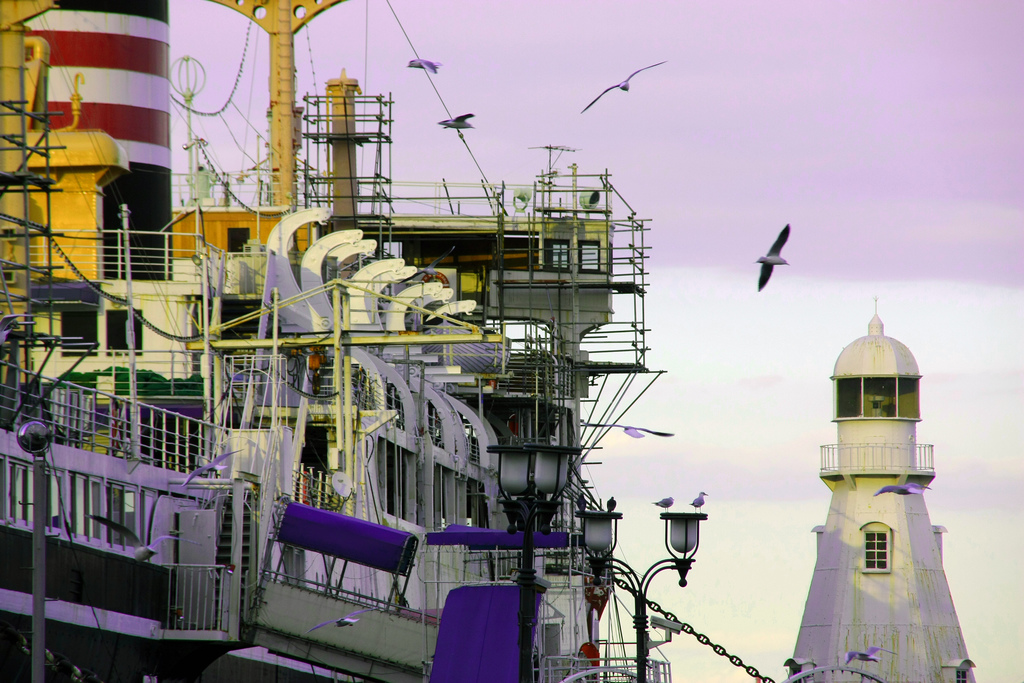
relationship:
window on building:
[191, 201, 312, 290] [115, 157, 610, 445]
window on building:
[833, 363, 870, 413] [783, 318, 974, 675]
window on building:
[845, 371, 900, 421] [772, 335, 967, 614]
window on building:
[852, 515, 896, 576] [783, 318, 974, 675]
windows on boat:
[571, 234, 598, 263] [237, 190, 633, 661]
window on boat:
[92, 297, 144, 350] [20, 245, 388, 660]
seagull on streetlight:
[658, 490, 674, 516] [576, 509, 710, 678]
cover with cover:
[277, 501, 419, 573] [286, 502, 414, 572]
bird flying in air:
[754, 222, 793, 292] [169, 1, 991, 676]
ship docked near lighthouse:
[16, 16, 656, 658] [783, 290, 976, 679]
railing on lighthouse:
[802, 421, 962, 493] [755, 317, 980, 678]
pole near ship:
[567, 488, 721, 677] [16, 16, 656, 658]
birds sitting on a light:
[574, 485, 709, 514] [576, 513, 710, 680]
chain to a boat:
[602, 548, 769, 678] [1, 4, 667, 679]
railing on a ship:
[49, 371, 227, 465] [16, 16, 656, 658]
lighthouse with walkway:
[777, 312, 972, 680] [811, 434, 945, 499]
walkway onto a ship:
[243, 479, 462, 661] [16, 16, 656, 658]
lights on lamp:
[565, 500, 708, 559] [573, 488, 717, 683]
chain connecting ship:
[593, 555, 779, 674] [16, 16, 656, 658]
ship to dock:
[16, 16, 656, 658] [666, 635, 1012, 666]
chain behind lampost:
[593, 555, 779, 674] [567, 492, 734, 678]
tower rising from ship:
[223, 4, 358, 219] [16, 16, 656, 658]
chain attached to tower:
[169, 2, 263, 121] [228, 2, 343, 203]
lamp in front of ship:
[571, 485, 716, 671] [16, 16, 656, 658]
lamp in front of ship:
[485, 421, 578, 679] [16, 16, 656, 658]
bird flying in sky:
[746, 213, 799, 300] [169, 12, 1021, 678]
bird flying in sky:
[571, 38, 660, 116] [169, 12, 1021, 678]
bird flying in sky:
[440, 105, 479, 142] [169, 12, 1021, 678]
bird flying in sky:
[398, 34, 453, 86] [169, 12, 1021, 678]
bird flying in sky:
[736, 209, 821, 311] [169, 12, 1021, 678]